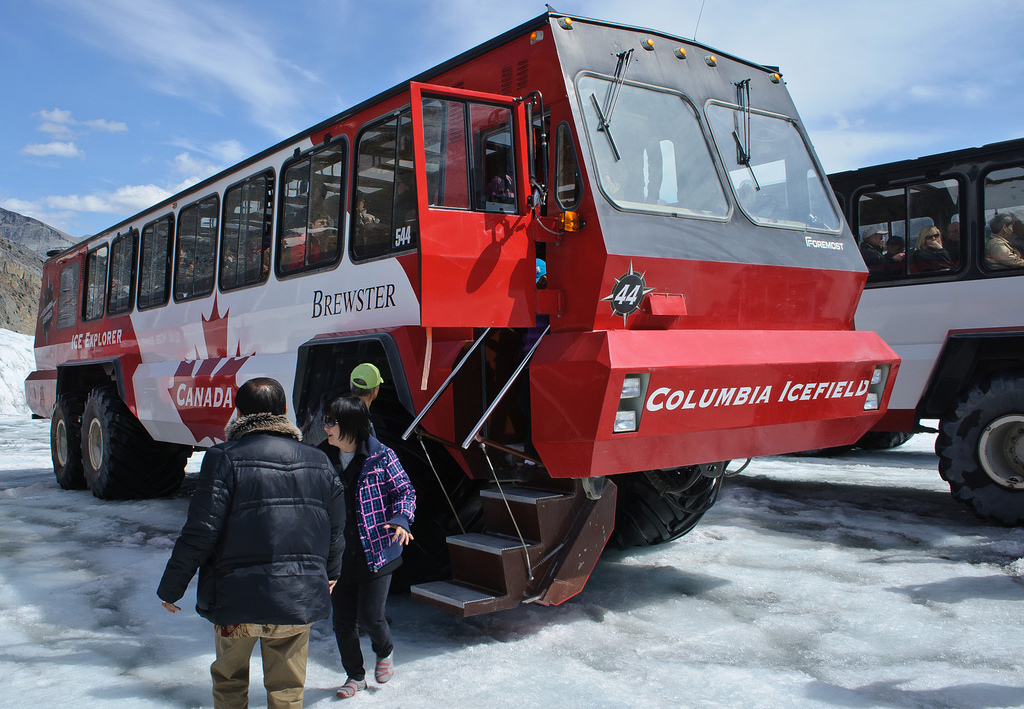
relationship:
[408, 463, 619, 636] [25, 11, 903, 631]
stairs attached to vehicle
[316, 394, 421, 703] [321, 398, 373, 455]
girl has hair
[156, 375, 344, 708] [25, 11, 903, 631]
men are boarding vehicle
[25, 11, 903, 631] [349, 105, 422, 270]
vehicle has window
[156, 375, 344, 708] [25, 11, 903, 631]
men are waiting on vehicle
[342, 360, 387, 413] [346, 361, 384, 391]
man wearing baseball cap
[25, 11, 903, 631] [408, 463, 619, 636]
vehicle has stairs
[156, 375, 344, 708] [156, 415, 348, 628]
men have coat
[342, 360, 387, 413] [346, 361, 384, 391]
man has baseball cap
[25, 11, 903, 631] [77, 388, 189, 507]
vehicle has tires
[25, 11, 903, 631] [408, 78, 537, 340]
vehicle has door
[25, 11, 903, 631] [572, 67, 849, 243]
vehicle has windshield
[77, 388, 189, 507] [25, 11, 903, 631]
tires are on vehicle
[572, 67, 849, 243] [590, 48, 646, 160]
windshield have wipers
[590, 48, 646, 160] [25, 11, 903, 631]
wipers are on vehicle